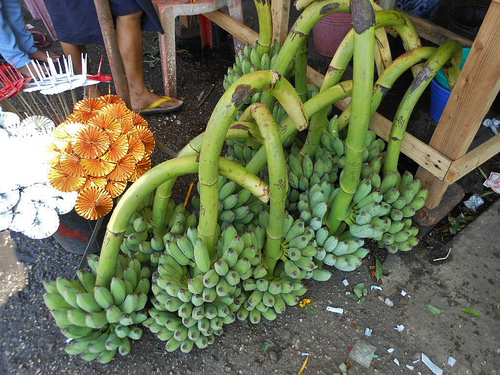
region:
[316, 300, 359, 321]
white piece of debris on ground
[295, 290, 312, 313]
yellow paper on ground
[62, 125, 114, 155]
gold colored round ridge object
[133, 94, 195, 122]
yellow flip flop on feet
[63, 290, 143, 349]
bunch of green bananas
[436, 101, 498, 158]
piece of wooden box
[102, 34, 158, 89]
portion of human leg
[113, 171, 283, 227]
thick green banana stalk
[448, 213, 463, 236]
portion of dirt on ground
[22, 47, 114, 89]
pointy white spikes on ground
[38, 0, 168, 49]
man wears blue sarong, yellow zoris [aka flip-flops]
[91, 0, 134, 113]
man is leaning on pole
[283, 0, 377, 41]
banana stalk has several bruises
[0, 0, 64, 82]
person behind man wears sky blue pants, bare feet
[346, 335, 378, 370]
tiny, often nefarious plastic bag amid trash on ground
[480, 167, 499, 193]
somewhat crumpled label is red+white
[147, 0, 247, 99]
man in sarong stands beside tatty plastic chair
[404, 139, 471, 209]
wooden table held together by visible pounded nails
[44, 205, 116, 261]
black bucket with dark red paint stripes holds gold, silver foil umbrellas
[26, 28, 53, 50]
woman's flip-flop [aka zori] is pink, behind person at top left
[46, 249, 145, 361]
bunch of unripened green bananas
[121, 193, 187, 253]
bunch of unripened green bananas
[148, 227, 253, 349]
bunch of unripened green bananas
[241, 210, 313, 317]
bunch of unripened green bananas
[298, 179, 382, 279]
bunch of unripened green bananas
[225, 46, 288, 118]
bunch of unripened green bananas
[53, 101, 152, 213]
bouquet of orange handmade paper flowers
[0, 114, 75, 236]
bouquet of silver handmade paper flowers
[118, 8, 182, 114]
leg with yellow flip flop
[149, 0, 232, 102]
dirty white plastic stool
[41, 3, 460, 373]
A bunch of unripe banana trees.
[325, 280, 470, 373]
Litter on the ground.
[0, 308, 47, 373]
A rough patch of paved ground.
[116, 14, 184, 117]
The shin of a woman's leg.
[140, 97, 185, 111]
A yellow flip flop on the persons foot.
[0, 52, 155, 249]
Colorful items next to the banana trees.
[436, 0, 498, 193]
A light wooden slat of a table.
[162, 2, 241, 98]
The glittery pink and white legs of a chair.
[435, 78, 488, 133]
A blue bucket under stable.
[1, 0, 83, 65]
A person wearing blue pants.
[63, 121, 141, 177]
the plant is oarange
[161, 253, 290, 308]
the bananas are green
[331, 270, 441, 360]
dirt on the floor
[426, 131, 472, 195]
the material is wood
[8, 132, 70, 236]
the flowers are white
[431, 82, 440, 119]
the bucket is blue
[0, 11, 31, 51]
the trousers are green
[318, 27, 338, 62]
the bucket is orange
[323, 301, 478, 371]
ground is grey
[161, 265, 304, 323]
the bananas are not ripe